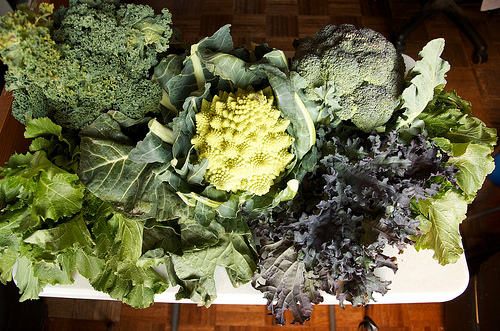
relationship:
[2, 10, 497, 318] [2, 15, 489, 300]
vegetables on table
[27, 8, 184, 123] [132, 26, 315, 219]
broccoli to left of cabbage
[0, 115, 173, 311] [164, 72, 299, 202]
vegetables on lower left of vegetable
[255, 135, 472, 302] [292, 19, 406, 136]
vegetable under broccoli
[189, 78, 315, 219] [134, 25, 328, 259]
cabbage surrounded by leaves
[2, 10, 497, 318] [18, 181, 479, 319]
vegetables on tray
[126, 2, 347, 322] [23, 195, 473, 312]
broccoli on tray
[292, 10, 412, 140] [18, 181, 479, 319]
broccoli on tray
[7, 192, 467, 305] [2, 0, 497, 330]
tray on table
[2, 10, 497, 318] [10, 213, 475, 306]
vegetables on plate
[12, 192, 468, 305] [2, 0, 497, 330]
tray on top of table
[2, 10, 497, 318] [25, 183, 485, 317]
vegetables laying on board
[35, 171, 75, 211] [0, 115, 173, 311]
line running along vegetables